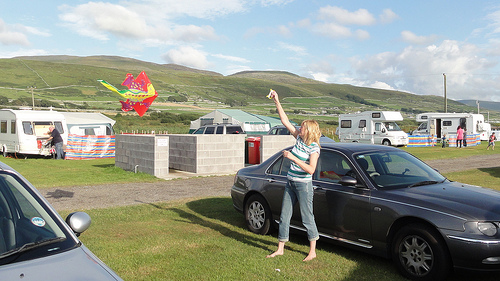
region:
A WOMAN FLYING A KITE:
[93, 68, 338, 263]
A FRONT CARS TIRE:
[384, 210, 459, 278]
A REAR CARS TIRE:
[235, 184, 271, 241]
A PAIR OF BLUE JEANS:
[275, 172, 322, 247]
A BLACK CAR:
[227, 134, 491, 276]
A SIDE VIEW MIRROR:
[58, 204, 105, 241]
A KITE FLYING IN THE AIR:
[91, 70, 174, 123]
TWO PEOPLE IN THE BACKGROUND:
[452, 119, 499, 149]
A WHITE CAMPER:
[330, 105, 430, 153]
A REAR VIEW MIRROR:
[377, 152, 398, 166]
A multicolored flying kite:
[93, 70, 160, 117]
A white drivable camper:
[337, 110, 407, 147]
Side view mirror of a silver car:
[66, 210, 91, 232]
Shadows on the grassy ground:
[161, 197, 233, 238]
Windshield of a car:
[358, 148, 439, 188]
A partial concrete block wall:
[111, 132, 242, 174]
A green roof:
[225, 107, 267, 122]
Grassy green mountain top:
[26, 53, 168, 70]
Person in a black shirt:
[46, 122, 63, 157]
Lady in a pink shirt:
[456, 123, 466, 149]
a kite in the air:
[90, 56, 172, 127]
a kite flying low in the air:
[75, 48, 161, 113]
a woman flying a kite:
[50, 38, 376, 252]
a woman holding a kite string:
[86, 61, 333, 245]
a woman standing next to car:
[221, 103, 476, 278]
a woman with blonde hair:
[257, 85, 340, 252]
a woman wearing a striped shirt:
[251, 106, 333, 246]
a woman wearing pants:
[249, 93, 339, 263]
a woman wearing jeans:
[266, 104, 335, 275]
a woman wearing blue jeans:
[259, 115, 330, 268]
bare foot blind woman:
[248, 60, 337, 271]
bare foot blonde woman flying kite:
[66, 45, 361, 268]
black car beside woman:
[226, 65, 499, 265]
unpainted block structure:
[108, 128, 312, 183]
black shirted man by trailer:
[4, 98, 73, 173]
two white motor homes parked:
[325, 94, 499, 158]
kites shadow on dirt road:
[47, 177, 90, 207]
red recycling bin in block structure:
[247, 134, 261, 170]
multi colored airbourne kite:
[90, 63, 166, 127]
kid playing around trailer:
[484, 128, 499, 148]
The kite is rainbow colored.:
[90, 65, 165, 132]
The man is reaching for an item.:
[32, 114, 66, 157]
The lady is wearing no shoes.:
[260, 92, 330, 269]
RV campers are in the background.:
[335, 107, 499, 157]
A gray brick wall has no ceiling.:
[118, 122, 189, 183]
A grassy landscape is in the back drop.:
[172, 57, 277, 111]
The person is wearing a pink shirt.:
[450, 120, 467, 146]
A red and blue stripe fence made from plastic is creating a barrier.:
[76, 132, 106, 174]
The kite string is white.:
[261, 77, 288, 127]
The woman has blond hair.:
[282, 107, 329, 172]